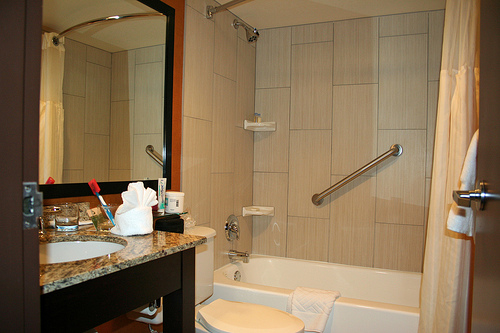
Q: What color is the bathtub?
A: White.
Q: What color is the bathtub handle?
A: Silver.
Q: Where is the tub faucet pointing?
A: Down.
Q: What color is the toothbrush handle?
A: Blue.